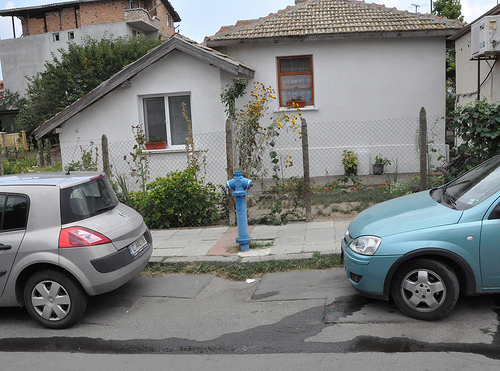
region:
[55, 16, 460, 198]
Small grey house behind a metallic fence.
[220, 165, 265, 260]
Blue fire hydrant standing between two parked cars.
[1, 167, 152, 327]
Grey car parked on the street.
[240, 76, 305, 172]
Tall plant with yellow flowers on the front yard.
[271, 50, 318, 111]
Window frame is red.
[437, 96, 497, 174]
Climbing plant growing along the fence.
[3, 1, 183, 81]
Tall house being built in the background.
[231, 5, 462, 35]
Roof tiles are grey and light brown.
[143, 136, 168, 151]
Window plants in a red pot.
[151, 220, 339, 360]
Street and sidewalk are in a bad shape.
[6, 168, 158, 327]
Gray car parked down hill on side of street.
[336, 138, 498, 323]
Blue car parked down hill on side of street.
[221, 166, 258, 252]
Blue fire hydrant on sidewalk.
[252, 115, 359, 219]
Wire fence running on side of house.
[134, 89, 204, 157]
Window on side of house.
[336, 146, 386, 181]
Potted plants sitting on ground next to house.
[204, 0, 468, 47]
Roof of house next to street.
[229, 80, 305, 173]
Flowers growing in yard of house.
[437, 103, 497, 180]
Vine growing on wire fence.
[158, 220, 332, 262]
Paved sidewalk next to street.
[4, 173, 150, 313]
silver car parked along a street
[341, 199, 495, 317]
blue car parked along the street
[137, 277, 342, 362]
uneven pavement on the street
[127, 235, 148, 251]
white license plate on a silver car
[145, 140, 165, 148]
brown flower box on a windowsill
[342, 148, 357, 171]
potted plant near the side of a house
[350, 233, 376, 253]
front headlight of a blue car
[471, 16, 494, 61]
air conditioner unit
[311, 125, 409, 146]
wire fence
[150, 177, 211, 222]
green plants in front of the fence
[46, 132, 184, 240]
The fence post is wood.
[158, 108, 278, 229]
The fence post is wood.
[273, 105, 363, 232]
The fence post is wood.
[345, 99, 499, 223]
The fence post is wood.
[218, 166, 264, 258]
The fire hydrant is blue.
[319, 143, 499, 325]
The car is blue.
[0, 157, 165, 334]
The car is silver.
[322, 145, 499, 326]
Front wheel on car turns in.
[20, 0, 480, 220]
The house is white.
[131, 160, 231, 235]
The bush is green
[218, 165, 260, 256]
A blue fire hydrant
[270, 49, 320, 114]
Window on a house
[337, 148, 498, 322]
The blue front of a car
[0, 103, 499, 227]
A fence in front of the house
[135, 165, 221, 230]
A small green bush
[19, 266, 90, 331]
A round rubber tire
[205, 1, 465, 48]
The roof of a house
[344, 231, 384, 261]
Headlight on front of a car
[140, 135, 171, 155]
Flower pot on a window sill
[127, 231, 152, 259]
License plate on back of a car